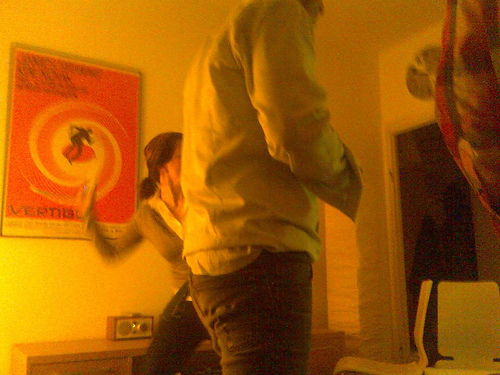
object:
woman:
[80, 131, 210, 374]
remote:
[71, 165, 98, 209]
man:
[179, 1, 364, 374]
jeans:
[187, 249, 313, 374]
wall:
[0, 0, 496, 374]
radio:
[106, 312, 155, 339]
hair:
[135, 130, 183, 198]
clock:
[404, 41, 439, 100]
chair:
[334, 281, 433, 374]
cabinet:
[12, 330, 347, 375]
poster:
[1, 40, 147, 240]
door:
[388, 120, 481, 363]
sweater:
[83, 199, 190, 283]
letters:
[10, 52, 106, 224]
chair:
[424, 280, 500, 375]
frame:
[383, 121, 476, 356]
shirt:
[183, 0, 363, 278]